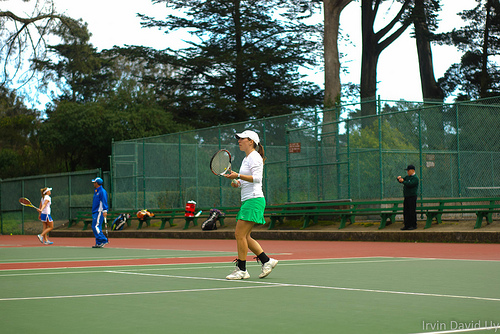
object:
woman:
[226, 130, 279, 280]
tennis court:
[0, 235, 500, 334]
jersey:
[238, 150, 265, 201]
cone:
[235, 130, 259, 147]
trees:
[143, 1, 367, 112]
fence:
[111, 94, 384, 221]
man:
[396, 164, 419, 230]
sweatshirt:
[396, 173, 419, 195]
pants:
[403, 199, 416, 229]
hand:
[223, 169, 238, 180]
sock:
[236, 259, 247, 271]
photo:
[3, 230, 496, 332]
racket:
[210, 149, 242, 189]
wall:
[226, 120, 299, 167]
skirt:
[235, 196, 267, 224]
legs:
[471, 212, 483, 229]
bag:
[201, 210, 221, 231]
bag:
[184, 200, 198, 218]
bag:
[135, 209, 156, 221]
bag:
[111, 212, 131, 230]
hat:
[404, 164, 417, 169]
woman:
[38, 188, 55, 243]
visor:
[42, 187, 53, 194]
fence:
[0, 167, 104, 235]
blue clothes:
[90, 186, 108, 213]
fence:
[377, 94, 500, 220]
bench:
[67, 197, 500, 231]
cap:
[234, 130, 261, 146]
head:
[238, 129, 260, 152]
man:
[90, 177, 109, 247]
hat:
[403, 164, 415, 171]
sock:
[257, 252, 270, 265]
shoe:
[225, 269, 251, 280]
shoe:
[257, 257, 279, 277]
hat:
[90, 176, 103, 186]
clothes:
[92, 211, 108, 244]